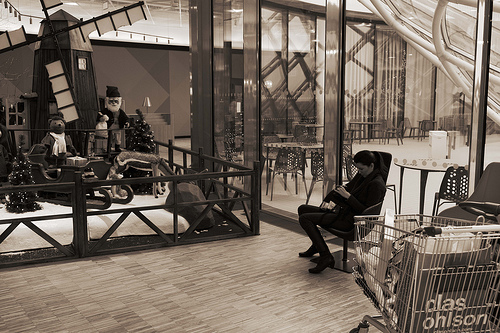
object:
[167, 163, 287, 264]
design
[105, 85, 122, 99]
hat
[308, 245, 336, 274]
boots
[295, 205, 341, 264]
pants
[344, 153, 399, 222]
chair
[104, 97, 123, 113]
beard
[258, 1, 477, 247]
glass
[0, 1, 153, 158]
windmill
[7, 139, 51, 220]
tree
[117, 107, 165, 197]
trees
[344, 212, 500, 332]
trolley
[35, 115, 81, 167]
doll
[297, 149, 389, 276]
woman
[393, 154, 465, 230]
tables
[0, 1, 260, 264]
decorations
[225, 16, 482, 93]
reflection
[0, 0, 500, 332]
scene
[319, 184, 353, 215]
bag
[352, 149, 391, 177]
hair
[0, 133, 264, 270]
fence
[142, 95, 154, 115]
lamp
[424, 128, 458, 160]
bin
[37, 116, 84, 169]
bear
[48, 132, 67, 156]
scarf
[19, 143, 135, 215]
sleigh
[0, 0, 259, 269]
display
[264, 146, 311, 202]
chairs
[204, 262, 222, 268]
line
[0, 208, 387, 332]
floor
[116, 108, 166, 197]
christmas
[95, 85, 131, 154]
santa